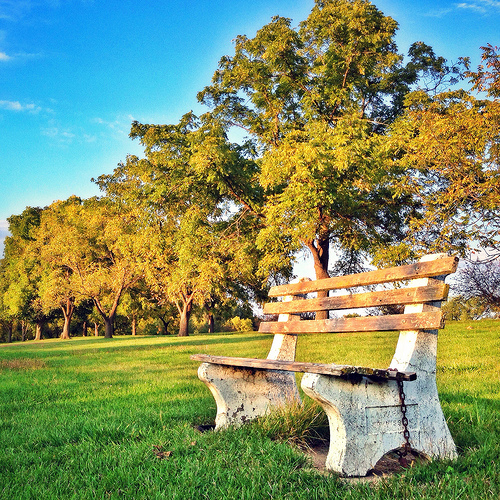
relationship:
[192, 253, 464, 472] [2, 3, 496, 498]
bench in park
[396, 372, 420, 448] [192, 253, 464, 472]
chain hanging from bench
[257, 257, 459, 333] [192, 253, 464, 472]
back of bench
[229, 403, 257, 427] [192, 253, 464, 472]
peeling paint on bench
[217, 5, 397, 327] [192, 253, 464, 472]
tree behind bench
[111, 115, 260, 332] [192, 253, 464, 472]
tree behind bench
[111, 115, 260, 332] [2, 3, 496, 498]
tree in park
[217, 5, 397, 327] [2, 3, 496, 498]
tree in park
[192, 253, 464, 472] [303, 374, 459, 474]
bench has legs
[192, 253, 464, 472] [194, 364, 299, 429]
bench has legs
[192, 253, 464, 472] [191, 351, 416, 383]
bench has a seat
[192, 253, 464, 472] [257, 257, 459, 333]
bench has a back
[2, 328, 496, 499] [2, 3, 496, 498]
grass in park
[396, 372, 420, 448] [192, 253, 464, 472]
chain on bench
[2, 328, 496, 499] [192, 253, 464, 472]
grass in front of bench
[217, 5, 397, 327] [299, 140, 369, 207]
tree has leaves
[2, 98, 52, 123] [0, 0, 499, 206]
clouds are in sky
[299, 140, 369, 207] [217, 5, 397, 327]
leaves are on tree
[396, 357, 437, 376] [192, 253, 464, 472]
crack on bench